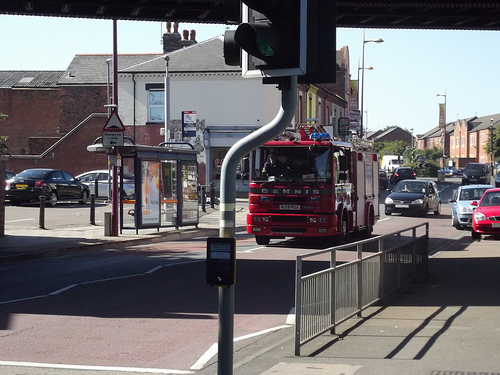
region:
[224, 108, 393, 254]
red truck on the road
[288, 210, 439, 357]
railing along the sidewalk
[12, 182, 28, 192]
yellow license plate on the back of the vehicle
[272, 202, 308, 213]
white and black license plate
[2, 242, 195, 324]
jagged white line on the road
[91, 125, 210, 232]
area to wait for buses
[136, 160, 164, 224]
advertisement on the bus terminal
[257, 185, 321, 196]
writing on the front of the truck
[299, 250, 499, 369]
shadows on the ground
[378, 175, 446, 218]
This is a car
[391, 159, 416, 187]
This is a car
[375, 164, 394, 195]
This is a car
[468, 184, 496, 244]
This is a car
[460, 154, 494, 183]
This is a car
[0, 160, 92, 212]
This is a car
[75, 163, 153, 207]
This is a car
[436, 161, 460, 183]
This is a car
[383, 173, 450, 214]
This is a car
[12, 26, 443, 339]
this is an urban setting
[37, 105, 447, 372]
this is a city street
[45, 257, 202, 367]
the street is pavement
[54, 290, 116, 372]
the street is gray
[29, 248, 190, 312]
these are white lines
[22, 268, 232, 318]
the lines zig-zag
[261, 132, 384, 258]
this is a fire truck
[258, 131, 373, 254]
the fire truck is red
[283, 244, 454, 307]
this is a metal railing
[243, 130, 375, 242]
a red fire truck driving down the road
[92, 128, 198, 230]
a long bus stop next to the road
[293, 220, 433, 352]
the long narrow metal fence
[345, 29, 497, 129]
the sunny blue sky with no clouds in it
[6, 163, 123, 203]
the cars sitting in the road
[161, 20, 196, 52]
the chimneys on top of the building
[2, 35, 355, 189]
some assorted building across the street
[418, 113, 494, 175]
a row of houses off to the side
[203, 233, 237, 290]
a box on the metal pole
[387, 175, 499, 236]
more cars going down the road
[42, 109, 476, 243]
cars on the street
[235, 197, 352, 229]
the bus is red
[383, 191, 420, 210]
the car is black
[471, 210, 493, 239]
the car is red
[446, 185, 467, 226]
the car is silver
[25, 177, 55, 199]
the car is black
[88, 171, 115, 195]
the car is white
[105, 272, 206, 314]
the area is shaded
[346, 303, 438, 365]
reflection of the fence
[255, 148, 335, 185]
widnsheild of the bus